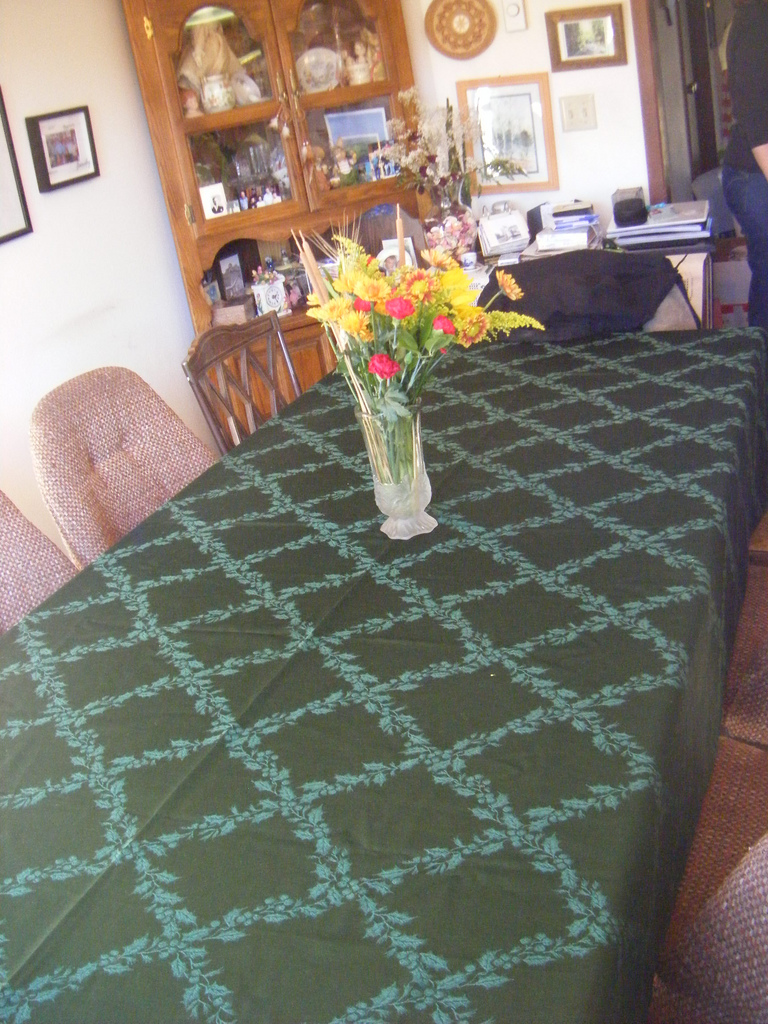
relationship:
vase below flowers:
[346, 401, 459, 555] [287, 232, 493, 413]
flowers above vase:
[287, 232, 493, 413] [346, 401, 459, 555]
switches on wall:
[554, 87, 609, 137] [0, 3, 623, 500]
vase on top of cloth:
[346, 401, 459, 555] [0, 326, 750, 1023]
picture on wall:
[21, 98, 109, 214] [0, 3, 623, 500]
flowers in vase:
[287, 232, 493, 413] [346, 401, 459, 555]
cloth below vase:
[0, 326, 750, 1023] [346, 401, 459, 555]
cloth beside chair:
[0, 326, 750, 1023] [163, 309, 317, 452]